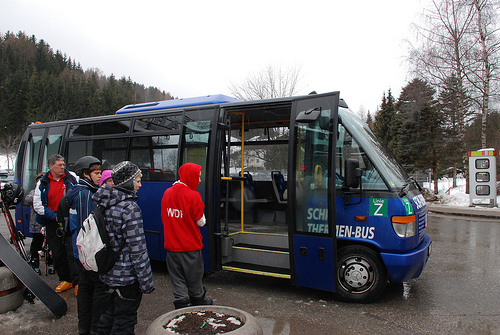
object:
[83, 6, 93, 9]
clouds sky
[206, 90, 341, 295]
open door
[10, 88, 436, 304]
bus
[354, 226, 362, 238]
letter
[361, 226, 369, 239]
letter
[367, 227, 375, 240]
letter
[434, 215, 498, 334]
moisture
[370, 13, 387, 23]
clouds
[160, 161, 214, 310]
man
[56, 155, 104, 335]
man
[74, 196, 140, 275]
backpack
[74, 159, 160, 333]
person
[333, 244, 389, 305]
tire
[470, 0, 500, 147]
trees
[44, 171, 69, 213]
shirt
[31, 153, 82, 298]
man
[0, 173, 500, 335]
ground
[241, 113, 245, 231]
pole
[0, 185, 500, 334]
road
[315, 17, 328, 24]
clouds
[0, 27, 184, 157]
hill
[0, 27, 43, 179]
trees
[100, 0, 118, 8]
clouds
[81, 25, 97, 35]
clouds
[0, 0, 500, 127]
sky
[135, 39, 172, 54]
cloud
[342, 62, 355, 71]
clouds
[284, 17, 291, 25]
clouds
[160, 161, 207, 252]
hoodie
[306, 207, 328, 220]
name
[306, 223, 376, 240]
name